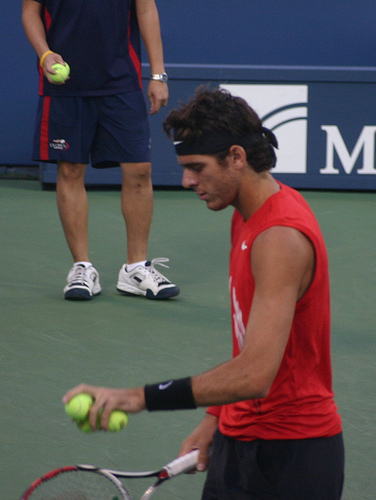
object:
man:
[57, 88, 347, 499]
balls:
[102, 411, 129, 433]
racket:
[16, 447, 204, 500]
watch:
[149, 72, 168, 83]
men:
[20, 0, 183, 304]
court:
[0, 182, 52, 468]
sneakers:
[115, 255, 181, 303]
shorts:
[30, 80, 153, 171]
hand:
[61, 382, 136, 434]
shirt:
[204, 179, 343, 447]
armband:
[142, 375, 197, 413]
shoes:
[61, 260, 102, 304]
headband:
[172, 127, 278, 158]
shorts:
[196, 429, 345, 499]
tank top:
[214, 182, 338, 442]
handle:
[159, 442, 213, 475]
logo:
[158, 380, 173, 391]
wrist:
[37, 42, 50, 59]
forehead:
[174, 127, 205, 161]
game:
[0, 0, 376, 500]